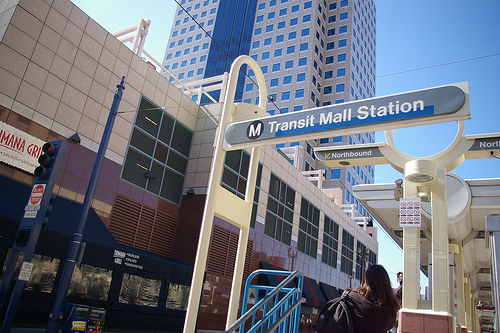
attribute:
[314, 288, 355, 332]
backpack — black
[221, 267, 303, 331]
rail — blue, metal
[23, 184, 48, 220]
sign — small, white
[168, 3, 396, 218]
windows — blue, glass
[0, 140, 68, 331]
light — blue, metal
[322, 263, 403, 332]
woman — large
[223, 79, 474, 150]
sign — blue, white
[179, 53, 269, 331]
pole — white, metal, tube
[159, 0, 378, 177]
building — blue, grey, glass, cement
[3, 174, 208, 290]
awning — fabric, blue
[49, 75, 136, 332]
pole — metal, blue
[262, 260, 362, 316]
awning — blue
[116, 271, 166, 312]
window — clear, plastic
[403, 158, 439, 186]
fixture — white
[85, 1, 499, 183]
sky — clear, blue